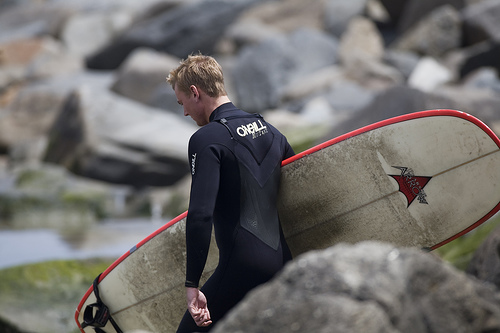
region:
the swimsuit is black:
[164, 100, 292, 292]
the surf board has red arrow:
[313, 119, 486, 241]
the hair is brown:
[171, 53, 233, 100]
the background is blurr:
[260, 47, 444, 100]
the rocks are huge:
[73, 86, 166, 168]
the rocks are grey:
[56, 88, 158, 164]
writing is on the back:
[230, 111, 271, 140]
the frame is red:
[341, 122, 374, 140]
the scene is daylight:
[4, 42, 496, 332]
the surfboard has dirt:
[316, 153, 399, 240]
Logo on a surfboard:
[388, 161, 433, 211]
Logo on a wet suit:
[230, 115, 265, 140]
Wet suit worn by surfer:
[165, 111, 295, 326]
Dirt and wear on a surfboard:
[295, 190, 345, 245]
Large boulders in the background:
[307, 1, 442, 86]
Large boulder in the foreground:
[186, 225, 496, 330]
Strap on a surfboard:
[75, 265, 140, 330]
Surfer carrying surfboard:
[150, 43, 315, 329]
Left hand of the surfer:
[172, 278, 219, 326]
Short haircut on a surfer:
[155, 43, 230, 113]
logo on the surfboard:
[363, 151, 441, 221]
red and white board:
[327, 108, 475, 228]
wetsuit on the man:
[174, 115, 292, 260]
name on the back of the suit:
[226, 115, 281, 162]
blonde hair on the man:
[166, 38, 231, 117]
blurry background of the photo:
[56, 76, 135, 148]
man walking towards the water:
[114, 26, 367, 302]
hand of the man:
[163, 272, 220, 330]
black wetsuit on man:
[148, 78, 318, 290]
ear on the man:
[181, 76, 213, 109]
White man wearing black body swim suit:
[162, 50, 292, 322]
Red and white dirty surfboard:
[78, 109, 496, 330]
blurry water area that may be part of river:
[4, 213, 150, 284]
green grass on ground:
[4, 266, 91, 300]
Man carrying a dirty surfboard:
[103, 52, 494, 274]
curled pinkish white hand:
[174, 279, 216, 326]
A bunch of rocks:
[43, 26, 163, 212]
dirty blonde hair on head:
[165, 51, 227, 96]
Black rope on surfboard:
[79, 279, 114, 331]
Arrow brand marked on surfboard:
[381, 144, 438, 220]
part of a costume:
[256, 237, 273, 266]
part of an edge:
[441, 226, 470, 257]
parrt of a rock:
[356, 280, 395, 325]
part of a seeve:
[178, 270, 193, 305]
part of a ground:
[1, 282, 40, 311]